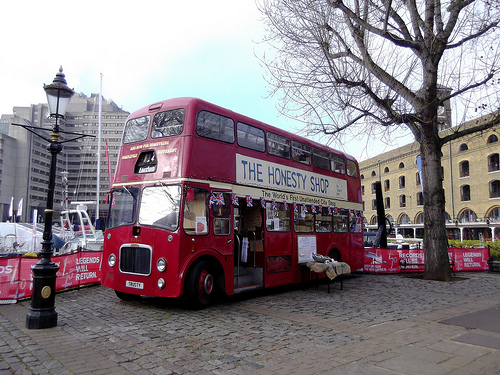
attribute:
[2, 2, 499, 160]
sky — blue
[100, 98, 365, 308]
bus — double decker, red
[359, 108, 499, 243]
building — tan, yellow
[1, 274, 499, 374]
ground — gray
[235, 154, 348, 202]
sign — white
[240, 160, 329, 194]
lettering — blue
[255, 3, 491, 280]
tree — bare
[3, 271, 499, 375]
pavement — cobbled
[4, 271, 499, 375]
street — cobble stone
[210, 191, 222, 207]
flag — string of union jack, british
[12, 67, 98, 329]
streetlight — tall